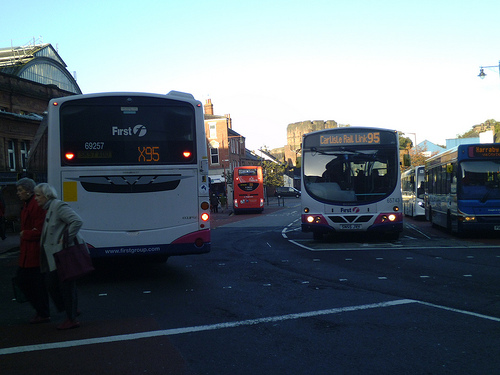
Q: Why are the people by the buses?
A: Waiting to load.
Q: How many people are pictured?
A: Two.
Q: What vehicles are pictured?
A: Buses.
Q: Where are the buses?
A: In the road.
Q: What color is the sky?
A: Blue.